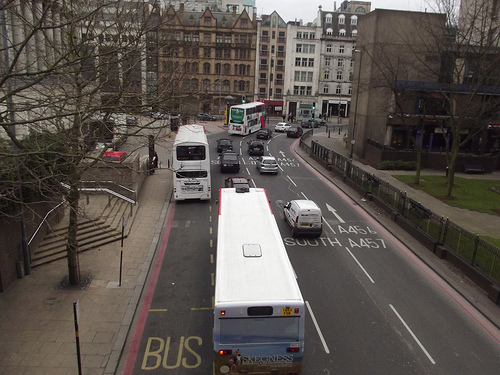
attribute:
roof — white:
[214, 187, 307, 306]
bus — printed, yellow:
[140, 335, 205, 370]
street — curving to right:
[116, 121, 500, 372]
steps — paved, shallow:
[30, 192, 136, 268]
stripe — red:
[119, 200, 177, 373]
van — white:
[282, 196, 323, 237]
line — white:
[265, 129, 436, 364]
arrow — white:
[324, 201, 345, 225]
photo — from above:
[0, 1, 499, 374]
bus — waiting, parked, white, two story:
[174, 126, 210, 200]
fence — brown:
[298, 127, 500, 300]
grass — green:
[395, 173, 499, 216]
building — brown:
[347, 8, 499, 172]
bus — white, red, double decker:
[228, 104, 268, 136]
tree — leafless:
[3, 0, 203, 288]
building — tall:
[157, 4, 263, 119]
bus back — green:
[229, 107, 245, 125]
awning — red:
[260, 100, 284, 107]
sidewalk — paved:
[0, 119, 222, 374]